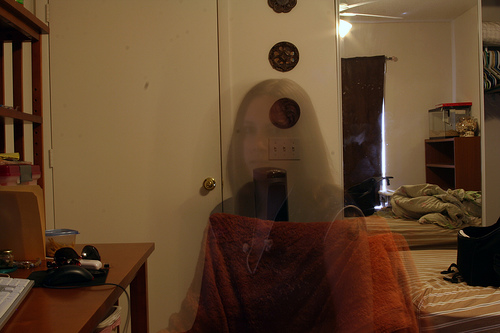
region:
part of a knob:
[228, 189, 232, 204]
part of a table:
[133, 271, 148, 293]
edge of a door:
[167, 195, 176, 212]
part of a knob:
[204, 178, 214, 193]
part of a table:
[144, 235, 146, 249]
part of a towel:
[385, 265, 393, 279]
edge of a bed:
[437, 250, 457, 275]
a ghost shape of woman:
[179, 79, 343, 286]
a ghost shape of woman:
[190, 76, 329, 292]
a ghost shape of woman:
[176, 83, 365, 323]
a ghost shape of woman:
[179, 67, 361, 312]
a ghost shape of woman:
[204, 78, 331, 284]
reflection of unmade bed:
[380, 173, 480, 240]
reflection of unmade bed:
[357, 170, 478, 244]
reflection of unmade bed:
[347, 177, 487, 259]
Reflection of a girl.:
[160, 75, 435, 325]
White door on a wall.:
[35, 3, 229, 328]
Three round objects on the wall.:
[262, 0, 305, 132]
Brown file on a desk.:
[0, 180, 52, 279]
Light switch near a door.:
[264, 132, 305, 163]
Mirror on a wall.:
[331, 2, 488, 251]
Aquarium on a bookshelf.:
[423, 101, 475, 135]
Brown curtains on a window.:
[340, 48, 397, 212]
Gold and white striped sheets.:
[390, 245, 498, 321]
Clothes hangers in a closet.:
[483, 40, 498, 92]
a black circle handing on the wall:
[269, 97, 301, 124]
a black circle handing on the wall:
[269, 1, 299, 15]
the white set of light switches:
[269, 137, 298, 161]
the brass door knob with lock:
[201, 176, 216, 190]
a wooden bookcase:
[423, 136, 477, 195]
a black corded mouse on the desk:
[31, 266, 132, 328]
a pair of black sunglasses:
[54, 243, 104, 266]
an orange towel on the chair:
[164, 211, 415, 329]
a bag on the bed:
[455, 222, 497, 289]